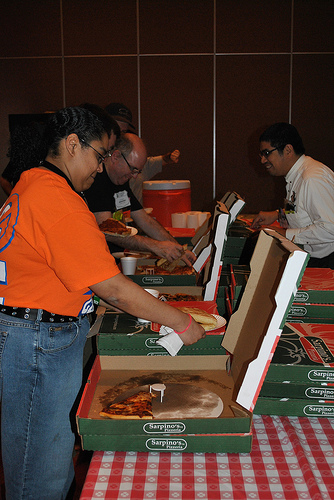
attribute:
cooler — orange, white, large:
[139, 177, 192, 229]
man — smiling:
[242, 121, 332, 268]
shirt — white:
[280, 153, 333, 260]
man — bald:
[85, 129, 201, 268]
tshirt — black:
[87, 166, 145, 215]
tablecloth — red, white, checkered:
[77, 415, 332, 499]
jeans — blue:
[0, 314, 89, 499]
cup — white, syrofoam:
[121, 254, 138, 275]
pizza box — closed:
[262, 322, 332, 385]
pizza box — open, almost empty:
[70, 228, 310, 438]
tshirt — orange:
[0, 168, 122, 320]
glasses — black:
[257, 144, 283, 159]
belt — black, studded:
[1, 302, 79, 324]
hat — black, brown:
[102, 100, 138, 130]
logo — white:
[143, 421, 190, 435]